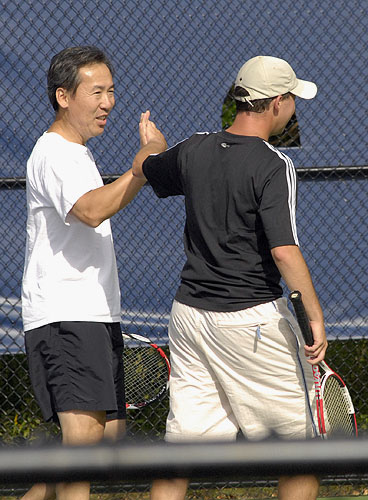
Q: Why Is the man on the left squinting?
A: It's bright outside.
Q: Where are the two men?
A: On a tennis court.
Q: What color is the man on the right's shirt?
A: Black.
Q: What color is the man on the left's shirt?
A: White.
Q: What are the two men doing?
A: Giving each other a high five.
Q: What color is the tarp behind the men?
A: Blue.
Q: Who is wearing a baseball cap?
A: The man on the right.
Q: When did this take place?
A: Daytime.